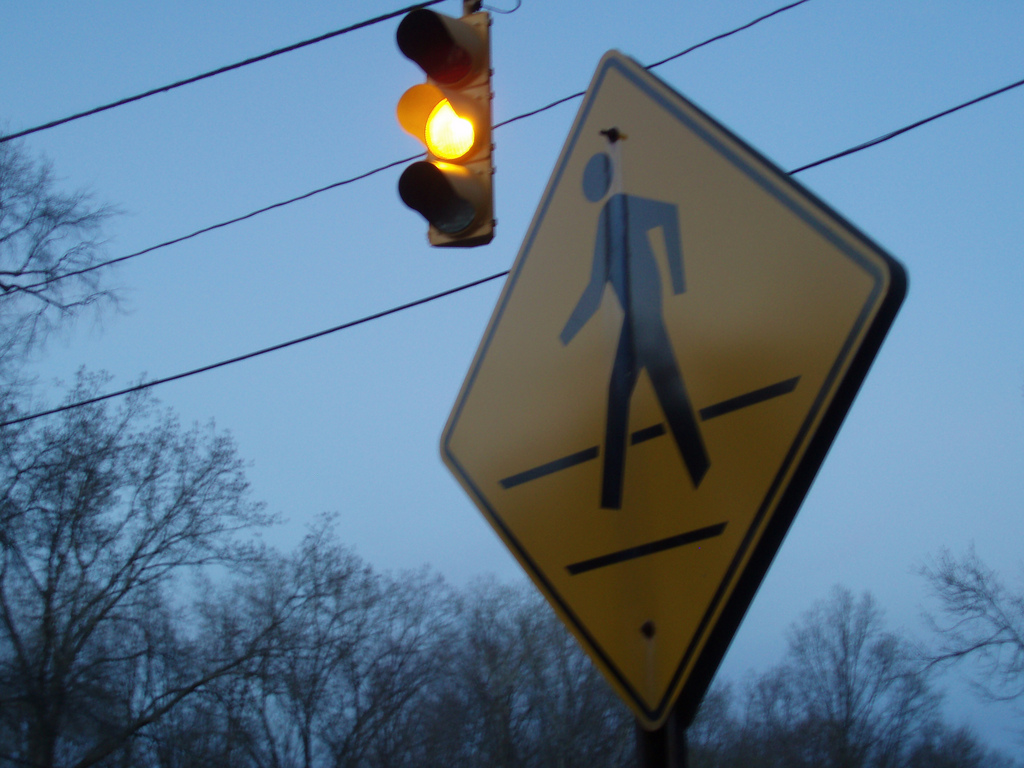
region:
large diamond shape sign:
[461, 44, 892, 719]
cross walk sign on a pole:
[430, 35, 914, 766]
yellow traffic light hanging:
[362, 16, 500, 263]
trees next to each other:
[11, 371, 451, 763]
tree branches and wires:
[5, 119, 202, 487]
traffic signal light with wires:
[298, 8, 549, 341]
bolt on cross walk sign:
[595, 122, 631, 146]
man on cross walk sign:
[560, 150, 722, 514]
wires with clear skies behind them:
[140, 73, 324, 337]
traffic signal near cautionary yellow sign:
[322, 16, 898, 719]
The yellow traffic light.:
[395, 73, 509, 154]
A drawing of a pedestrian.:
[549, 153, 723, 512]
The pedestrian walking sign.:
[424, 77, 944, 725]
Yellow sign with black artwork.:
[714, 241, 845, 444]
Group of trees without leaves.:
[19, 463, 406, 752]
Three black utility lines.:
[66, 73, 300, 402]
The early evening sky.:
[900, 248, 1022, 509]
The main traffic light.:
[343, 8, 515, 261]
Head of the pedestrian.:
[537, 154, 659, 205]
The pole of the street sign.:
[555, 718, 767, 766]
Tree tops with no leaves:
[1, 178, 381, 763]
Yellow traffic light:
[378, 1, 522, 265]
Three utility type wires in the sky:
[0, 0, 403, 424]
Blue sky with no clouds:
[0, 20, 1009, 504]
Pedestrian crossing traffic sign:
[408, 21, 930, 737]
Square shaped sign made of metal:
[427, 19, 914, 747]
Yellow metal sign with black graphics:
[422, 21, 931, 743]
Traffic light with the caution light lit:
[383, 0, 514, 256]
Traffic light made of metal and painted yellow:
[389, 1, 510, 261]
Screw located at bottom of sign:
[624, 615, 679, 653]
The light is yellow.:
[376, 2, 510, 255]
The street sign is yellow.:
[426, 48, 917, 738]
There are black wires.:
[8, 2, 1018, 238]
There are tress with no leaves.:
[10, 128, 505, 765]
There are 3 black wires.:
[6, 4, 1016, 450]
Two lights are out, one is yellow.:
[382, 1, 512, 257]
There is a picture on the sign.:
[426, 49, 913, 733]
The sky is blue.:
[6, 0, 1019, 722]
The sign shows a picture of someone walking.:
[429, 40, 914, 742]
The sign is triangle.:
[438, 40, 938, 758]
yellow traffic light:
[378, 73, 499, 157]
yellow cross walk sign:
[449, 35, 861, 732]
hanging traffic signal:
[370, 6, 507, 253]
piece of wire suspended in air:
[78, 31, 338, 111]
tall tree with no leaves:
[6, 433, 221, 766]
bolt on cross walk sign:
[623, 616, 668, 646]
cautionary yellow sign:
[385, 44, 927, 759]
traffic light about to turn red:
[345, 3, 538, 251]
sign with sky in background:
[417, 36, 927, 729]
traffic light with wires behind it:
[340, 0, 517, 339]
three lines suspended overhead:
[115, 68, 351, 381]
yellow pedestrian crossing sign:
[494, 119, 830, 689]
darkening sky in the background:
[276, 380, 407, 491]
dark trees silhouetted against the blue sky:
[35, 437, 372, 742]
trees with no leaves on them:
[806, 605, 999, 745]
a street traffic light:
[402, 2, 508, 258]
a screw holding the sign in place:
[586, 112, 632, 150]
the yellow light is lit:
[390, 77, 499, 154]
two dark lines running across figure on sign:
[588, 137, 647, 371]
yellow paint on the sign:
[759, 242, 846, 303]